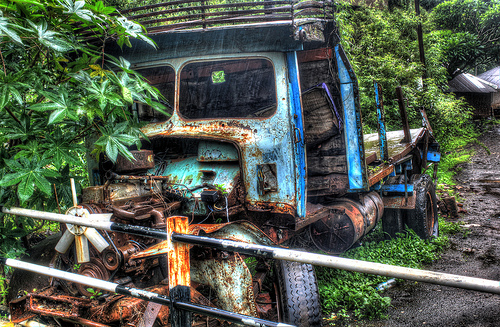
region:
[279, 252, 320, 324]
the tread on the tire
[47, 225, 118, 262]
the fan on the engine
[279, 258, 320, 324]
the front tire of the truck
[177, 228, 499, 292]
the hand rail in front of the truck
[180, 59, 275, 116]
the windshield on the truck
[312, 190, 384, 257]
the barrel under the truck bed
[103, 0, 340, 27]
the roof rack on the truck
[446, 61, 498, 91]
the roofs of the building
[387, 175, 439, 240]
the two back tires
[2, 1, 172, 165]
the leaves in front of the truck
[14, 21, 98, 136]
a bunch of wet green leaves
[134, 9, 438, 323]
an old broken blue truck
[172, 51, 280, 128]
the window of a blue truck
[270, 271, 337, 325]
the wheel of a blue truck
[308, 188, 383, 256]
the exhaust pipe of a blue truck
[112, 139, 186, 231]
the engine of a blue truck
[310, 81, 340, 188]
the interior of a blue truck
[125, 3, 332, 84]
the top part of a blue truck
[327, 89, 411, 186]
the bed of a blue truck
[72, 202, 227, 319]
a fence made out of metal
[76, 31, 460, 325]
a rusted old truck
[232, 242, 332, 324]
wheel of a truck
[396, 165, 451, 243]
wheel of a truck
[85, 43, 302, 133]
windows of a truck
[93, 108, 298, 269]
front of a truck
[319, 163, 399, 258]
canister of a truck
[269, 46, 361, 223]
side door of a truck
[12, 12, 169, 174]
bushes near a truck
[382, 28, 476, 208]
bushes near a road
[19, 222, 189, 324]
bunch of scraps on floor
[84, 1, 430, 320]
Old rusty truck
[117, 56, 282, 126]
Windshield of the old rusty truck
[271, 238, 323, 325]
Black tire on old truck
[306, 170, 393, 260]
Gas tank on old rusty truck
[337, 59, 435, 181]
Flat bed of old rusty truck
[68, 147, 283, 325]
Front end of wrecked rusty truck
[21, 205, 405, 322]
Fence railing in front of truck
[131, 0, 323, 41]
Railing on top of truck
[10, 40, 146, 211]
Green tree beside truck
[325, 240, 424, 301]
Green weeds under truck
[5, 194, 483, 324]
a bar in front of the truck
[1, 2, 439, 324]
the truck is broken down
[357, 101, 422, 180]
the truck bed is broken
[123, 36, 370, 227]
the truck cab is blue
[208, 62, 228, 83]
a green mark on the truck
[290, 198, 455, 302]
grass under the truck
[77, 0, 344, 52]
a fence on top of the truck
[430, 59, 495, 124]
a building at the end of the path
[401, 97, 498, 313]
a path behind the truck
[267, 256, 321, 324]
a wheel turned under the truck